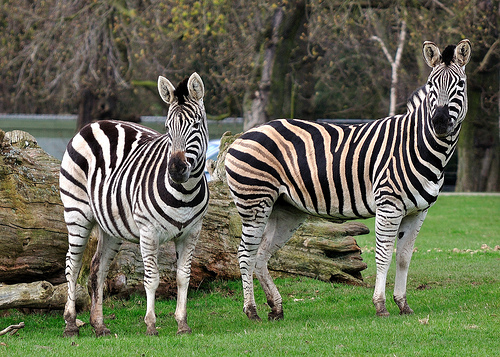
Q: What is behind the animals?
A: A fallen log.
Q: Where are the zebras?
A: On the grass.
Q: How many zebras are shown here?
A: 2.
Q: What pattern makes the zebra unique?
A: Stripes.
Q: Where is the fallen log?
A: Behind the zebras.